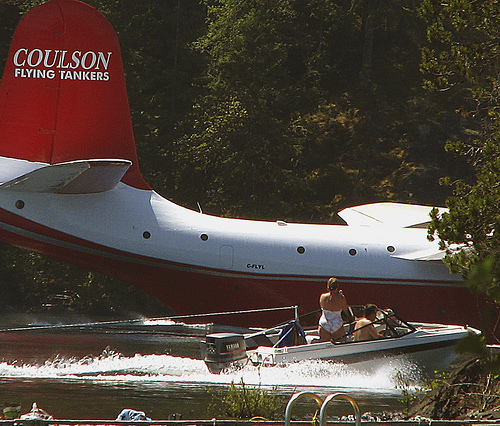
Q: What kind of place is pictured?
A: It is a river.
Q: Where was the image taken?
A: It was taken at the river.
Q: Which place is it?
A: It is a river.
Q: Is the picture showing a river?
A: Yes, it is showing a river.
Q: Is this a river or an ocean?
A: It is a river.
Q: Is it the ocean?
A: No, it is the river.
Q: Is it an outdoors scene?
A: Yes, it is outdoors.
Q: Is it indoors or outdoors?
A: It is outdoors.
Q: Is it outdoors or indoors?
A: It is outdoors.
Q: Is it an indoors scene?
A: No, it is outdoors.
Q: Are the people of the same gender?
A: No, they are both male and female.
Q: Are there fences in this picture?
A: No, there are no fences.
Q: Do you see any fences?
A: No, there are no fences.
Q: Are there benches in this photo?
A: No, there are no benches.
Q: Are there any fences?
A: No, there are no fences.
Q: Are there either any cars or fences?
A: No, there are no fences or cars.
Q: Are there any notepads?
A: No, there are no notepads.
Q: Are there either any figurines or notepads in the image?
A: No, there are no notepads or figurines.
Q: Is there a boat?
A: Yes, there is a boat.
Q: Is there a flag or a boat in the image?
A: Yes, there is a boat.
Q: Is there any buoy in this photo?
A: No, there are no buoys.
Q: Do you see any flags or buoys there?
A: No, there are no buoys or flags.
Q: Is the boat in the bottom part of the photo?
A: Yes, the boat is in the bottom of the image.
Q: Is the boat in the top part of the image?
A: No, the boat is in the bottom of the image.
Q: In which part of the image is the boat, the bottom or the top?
A: The boat is in the bottom of the image.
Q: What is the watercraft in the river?
A: The watercraft is a boat.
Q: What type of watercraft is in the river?
A: The watercraft is a boat.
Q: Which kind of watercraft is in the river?
A: The watercraft is a boat.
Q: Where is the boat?
A: The boat is in the river.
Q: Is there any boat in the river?
A: Yes, there is a boat in the river.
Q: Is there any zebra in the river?
A: No, there is a boat in the river.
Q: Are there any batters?
A: No, there are no batters.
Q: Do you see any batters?
A: No, there are no batters.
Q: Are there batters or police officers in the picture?
A: No, there are no batters or police officers.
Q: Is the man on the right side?
A: Yes, the man is on the right of the image.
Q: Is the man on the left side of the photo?
A: No, the man is on the right of the image.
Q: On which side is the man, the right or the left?
A: The man is on the right of the image.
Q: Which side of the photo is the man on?
A: The man is on the right of the image.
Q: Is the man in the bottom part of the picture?
A: Yes, the man is in the bottom of the image.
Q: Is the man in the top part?
A: No, the man is in the bottom of the image.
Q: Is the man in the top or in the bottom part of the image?
A: The man is in the bottom of the image.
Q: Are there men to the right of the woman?
A: Yes, there is a man to the right of the woman.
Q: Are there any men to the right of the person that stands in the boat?
A: Yes, there is a man to the right of the woman.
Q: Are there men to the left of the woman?
A: No, the man is to the right of the woman.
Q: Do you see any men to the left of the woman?
A: No, the man is to the right of the woman.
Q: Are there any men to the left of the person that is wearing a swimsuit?
A: No, the man is to the right of the woman.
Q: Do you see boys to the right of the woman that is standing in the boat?
A: No, there is a man to the right of the woman.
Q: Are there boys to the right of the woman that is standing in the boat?
A: No, there is a man to the right of the woman.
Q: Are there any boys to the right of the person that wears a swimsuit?
A: No, there is a man to the right of the woman.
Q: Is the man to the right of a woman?
A: Yes, the man is to the right of a woman.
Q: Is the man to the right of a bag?
A: No, the man is to the right of a woman.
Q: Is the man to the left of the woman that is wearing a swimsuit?
A: No, the man is to the right of the woman.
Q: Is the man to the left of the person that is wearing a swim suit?
A: No, the man is to the right of the woman.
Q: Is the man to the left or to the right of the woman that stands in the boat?
A: The man is to the right of the woman.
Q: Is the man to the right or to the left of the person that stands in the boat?
A: The man is to the right of the woman.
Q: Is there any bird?
A: No, there are no birds.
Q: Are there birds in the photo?
A: No, there are no birds.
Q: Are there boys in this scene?
A: No, there are no boys.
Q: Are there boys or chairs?
A: No, there are no boys or chairs.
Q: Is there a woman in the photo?
A: Yes, there is a woman.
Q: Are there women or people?
A: Yes, there is a woman.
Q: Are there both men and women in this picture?
A: Yes, there are both a woman and a man.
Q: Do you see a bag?
A: No, there are no bags.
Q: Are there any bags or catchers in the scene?
A: No, there are no bags or catchers.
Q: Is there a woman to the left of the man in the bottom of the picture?
A: Yes, there is a woman to the left of the man.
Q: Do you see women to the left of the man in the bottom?
A: Yes, there is a woman to the left of the man.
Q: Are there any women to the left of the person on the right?
A: Yes, there is a woman to the left of the man.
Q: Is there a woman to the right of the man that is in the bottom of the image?
A: No, the woman is to the left of the man.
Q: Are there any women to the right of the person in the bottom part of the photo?
A: No, the woman is to the left of the man.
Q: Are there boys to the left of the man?
A: No, there is a woman to the left of the man.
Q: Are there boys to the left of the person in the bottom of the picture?
A: No, there is a woman to the left of the man.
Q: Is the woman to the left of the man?
A: Yes, the woman is to the left of the man.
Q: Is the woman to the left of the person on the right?
A: Yes, the woman is to the left of the man.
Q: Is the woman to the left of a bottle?
A: No, the woman is to the left of the man.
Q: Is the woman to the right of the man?
A: No, the woman is to the left of the man.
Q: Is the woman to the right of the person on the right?
A: No, the woman is to the left of the man.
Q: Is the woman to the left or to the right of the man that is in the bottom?
A: The woman is to the left of the man.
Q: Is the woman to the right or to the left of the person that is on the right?
A: The woman is to the left of the man.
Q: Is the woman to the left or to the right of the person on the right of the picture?
A: The woman is to the left of the man.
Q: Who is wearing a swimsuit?
A: The woman is wearing a swimsuit.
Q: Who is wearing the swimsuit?
A: The woman is wearing a swimsuit.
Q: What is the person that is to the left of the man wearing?
A: The woman is wearing a swimsuit.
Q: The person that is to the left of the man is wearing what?
A: The woman is wearing a swimsuit.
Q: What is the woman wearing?
A: The woman is wearing a swimsuit.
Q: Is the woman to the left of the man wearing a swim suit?
A: Yes, the woman is wearing a swim suit.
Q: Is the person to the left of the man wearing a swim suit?
A: Yes, the woman is wearing a swim suit.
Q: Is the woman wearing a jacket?
A: No, the woman is wearing a swim suit.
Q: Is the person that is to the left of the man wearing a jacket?
A: No, the woman is wearing a swim suit.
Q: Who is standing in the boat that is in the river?
A: The woman is standing in the boat.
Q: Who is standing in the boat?
A: The woman is standing in the boat.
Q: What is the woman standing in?
A: The woman is standing in the boat.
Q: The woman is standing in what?
A: The woman is standing in the boat.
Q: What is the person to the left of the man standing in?
A: The woman is standing in the boat.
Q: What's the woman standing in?
A: The woman is standing in the boat.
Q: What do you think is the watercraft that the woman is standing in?
A: The watercraft is a boat.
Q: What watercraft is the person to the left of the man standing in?
A: The woman is standing in the boat.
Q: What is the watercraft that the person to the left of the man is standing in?
A: The watercraft is a boat.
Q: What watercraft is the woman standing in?
A: The woman is standing in the boat.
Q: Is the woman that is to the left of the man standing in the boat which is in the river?
A: Yes, the woman is standing in the boat.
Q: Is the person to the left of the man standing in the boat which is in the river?
A: Yes, the woman is standing in the boat.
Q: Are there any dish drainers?
A: No, there are no dish drainers.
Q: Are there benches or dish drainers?
A: No, there are no dish drainers or benches.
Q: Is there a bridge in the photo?
A: No, there are no bridges.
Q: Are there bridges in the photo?
A: No, there are no bridges.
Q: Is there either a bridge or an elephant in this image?
A: No, there are no bridges or elephants.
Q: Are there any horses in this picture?
A: No, there are no horses.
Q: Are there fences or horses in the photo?
A: No, there are no horses or fences.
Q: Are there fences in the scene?
A: No, there are no fences.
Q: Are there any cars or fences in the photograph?
A: No, there are no fences or cars.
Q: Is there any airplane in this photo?
A: Yes, there is an airplane.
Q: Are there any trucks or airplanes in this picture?
A: Yes, there is an airplane.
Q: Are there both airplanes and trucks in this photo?
A: No, there is an airplane but no trucks.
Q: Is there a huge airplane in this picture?
A: Yes, there is a huge airplane.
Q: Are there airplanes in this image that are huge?
A: Yes, there is an airplane that is huge.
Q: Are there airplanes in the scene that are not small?
A: Yes, there is a huge airplane.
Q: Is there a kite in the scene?
A: No, there are no kites.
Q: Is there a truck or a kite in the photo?
A: No, there are no kites or trucks.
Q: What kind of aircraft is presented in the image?
A: The aircraft is an airplane.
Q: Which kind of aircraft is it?
A: The aircraft is an airplane.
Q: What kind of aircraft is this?
A: This is an airplane.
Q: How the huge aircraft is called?
A: The aircraft is an airplane.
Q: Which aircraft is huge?
A: The aircraft is an airplane.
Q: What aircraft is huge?
A: The aircraft is an airplane.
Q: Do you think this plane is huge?
A: Yes, the plane is huge.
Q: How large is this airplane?
A: The airplane is huge.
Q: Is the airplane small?
A: No, the airplane is huge.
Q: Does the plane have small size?
A: No, the plane is huge.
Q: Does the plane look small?
A: No, the plane is huge.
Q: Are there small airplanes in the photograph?
A: No, there is an airplane but it is huge.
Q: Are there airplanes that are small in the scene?
A: No, there is an airplane but it is huge.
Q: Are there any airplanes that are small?
A: No, there is an airplane but it is huge.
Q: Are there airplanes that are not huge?
A: No, there is an airplane but it is huge.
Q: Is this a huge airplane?
A: Yes, this is a huge airplane.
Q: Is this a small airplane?
A: No, this is a huge airplane.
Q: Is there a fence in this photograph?
A: No, there are no fences.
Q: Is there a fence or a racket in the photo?
A: No, there are no fences or rackets.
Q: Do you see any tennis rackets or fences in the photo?
A: No, there are no fences or tennis rackets.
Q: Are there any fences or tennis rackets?
A: No, there are no fences or tennis rackets.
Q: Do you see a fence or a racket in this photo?
A: No, there are no fences or rackets.